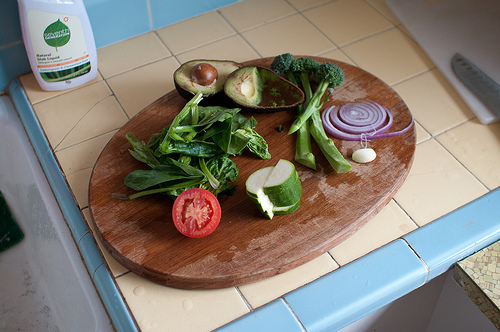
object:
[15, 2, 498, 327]
counter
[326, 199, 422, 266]
tile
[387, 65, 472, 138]
tile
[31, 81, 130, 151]
tile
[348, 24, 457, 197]
tantiles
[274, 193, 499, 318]
bluetiles